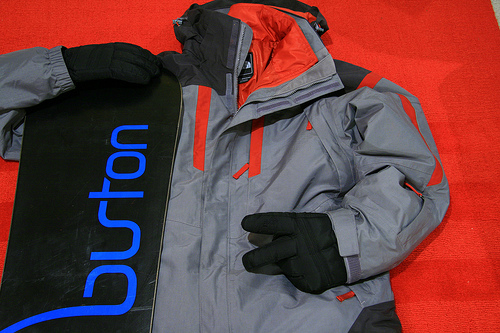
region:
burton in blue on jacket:
[53, 103, 159, 331]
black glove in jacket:
[242, 186, 351, 300]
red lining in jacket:
[230, 7, 317, 92]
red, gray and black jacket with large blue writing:
[5, 1, 420, 331]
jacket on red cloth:
[2, 2, 497, 330]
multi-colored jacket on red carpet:
[2, 2, 498, 331]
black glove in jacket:
[44, 29, 166, 94]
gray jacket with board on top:
[0, 4, 456, 331]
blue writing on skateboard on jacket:
[1, 29, 191, 331]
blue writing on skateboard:
[3, 62, 193, 330]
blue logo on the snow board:
[0, 114, 148, 327]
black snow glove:
[240, 211, 342, 289]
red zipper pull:
[230, 163, 249, 180]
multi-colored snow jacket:
[2, 8, 449, 331]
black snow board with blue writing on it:
[2, 43, 182, 332]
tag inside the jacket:
[239, 51, 254, 84]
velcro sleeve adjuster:
[328, 208, 358, 255]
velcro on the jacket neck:
[224, 20, 241, 107]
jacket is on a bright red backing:
[1, 2, 498, 324]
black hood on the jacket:
[172, 2, 327, 37]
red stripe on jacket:
[367, 70, 471, 215]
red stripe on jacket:
[244, 129, 276, 194]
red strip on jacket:
[191, 80, 228, 182]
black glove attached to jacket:
[49, 10, 189, 128]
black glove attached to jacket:
[239, 177, 369, 316]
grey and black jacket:
[46, 16, 468, 331]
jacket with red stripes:
[36, 8, 480, 328]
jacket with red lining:
[256, 8, 307, 63]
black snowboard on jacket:
[14, 12, 244, 328]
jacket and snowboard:
[10, 11, 453, 318]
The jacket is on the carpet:
[6, 5, 447, 330]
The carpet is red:
[1, 0, 491, 310]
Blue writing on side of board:
[10, 115, 155, 326]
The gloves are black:
[235, 205, 345, 285]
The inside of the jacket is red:
[200, 0, 320, 115]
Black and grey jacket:
[10, 0, 435, 325]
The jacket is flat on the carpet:
[10, 2, 445, 327]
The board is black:
[10, 5, 189, 330]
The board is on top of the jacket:
[6, 5, 446, 330]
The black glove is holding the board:
[7, 42, 194, 330]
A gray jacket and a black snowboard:
[119, 22, 449, 274]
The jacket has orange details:
[204, 117, 292, 190]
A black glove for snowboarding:
[230, 195, 362, 304]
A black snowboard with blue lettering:
[62, 116, 164, 260]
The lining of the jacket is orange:
[228, 12, 328, 94]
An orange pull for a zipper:
[229, 158, 251, 179]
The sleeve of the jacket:
[321, 67, 423, 281]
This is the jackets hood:
[156, 4, 331, 61]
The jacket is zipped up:
[197, 102, 228, 330]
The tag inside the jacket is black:
[233, 52, 265, 86]